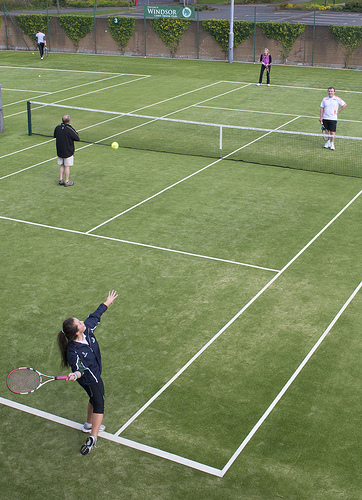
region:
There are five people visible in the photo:
[25, 16, 344, 417]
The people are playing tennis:
[16, 9, 357, 399]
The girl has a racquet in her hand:
[15, 301, 180, 497]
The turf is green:
[21, 166, 359, 458]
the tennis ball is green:
[27, 75, 189, 218]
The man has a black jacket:
[40, 98, 133, 223]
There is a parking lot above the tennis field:
[23, 5, 358, 77]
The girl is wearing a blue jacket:
[23, 274, 170, 453]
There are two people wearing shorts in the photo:
[24, 15, 359, 460]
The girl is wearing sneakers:
[34, 259, 168, 481]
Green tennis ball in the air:
[109, 141, 118, 148]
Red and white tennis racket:
[4, 366, 71, 393]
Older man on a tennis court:
[54, 114, 81, 186]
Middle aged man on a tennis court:
[319, 86, 347, 149]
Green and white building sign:
[143, 6, 195, 20]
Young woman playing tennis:
[46, 289, 120, 455]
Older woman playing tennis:
[256, 47, 270, 85]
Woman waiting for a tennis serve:
[258, 48, 272, 84]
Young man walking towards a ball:
[34, 31, 46, 58]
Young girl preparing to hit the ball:
[55, 288, 115, 452]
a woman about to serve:
[3, 279, 123, 469]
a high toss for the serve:
[105, 139, 125, 154]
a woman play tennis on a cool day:
[53, 278, 123, 459]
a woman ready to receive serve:
[247, 43, 278, 91]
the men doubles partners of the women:
[39, 68, 351, 201]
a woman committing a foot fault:
[4, 284, 127, 467]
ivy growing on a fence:
[10, 17, 321, 63]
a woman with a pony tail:
[4, 282, 125, 466]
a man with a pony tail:
[42, 109, 79, 185]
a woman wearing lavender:
[246, 46, 273, 92]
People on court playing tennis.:
[254, 45, 349, 161]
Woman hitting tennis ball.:
[6, 283, 144, 458]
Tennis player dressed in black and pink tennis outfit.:
[255, 48, 279, 88]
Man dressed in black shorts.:
[317, 116, 340, 132]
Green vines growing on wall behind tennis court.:
[148, 18, 252, 55]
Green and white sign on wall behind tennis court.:
[139, 0, 202, 27]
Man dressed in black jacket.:
[46, 120, 90, 161]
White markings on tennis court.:
[104, 177, 359, 478]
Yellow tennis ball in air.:
[104, 137, 131, 156]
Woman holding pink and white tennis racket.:
[5, 355, 78, 397]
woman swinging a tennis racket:
[3, 273, 132, 467]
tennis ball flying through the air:
[107, 127, 123, 161]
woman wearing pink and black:
[237, 42, 278, 90]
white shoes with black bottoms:
[73, 423, 111, 467]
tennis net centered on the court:
[23, 92, 360, 186]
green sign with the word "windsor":
[136, 5, 200, 32]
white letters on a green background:
[137, 3, 212, 28]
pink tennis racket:
[2, 358, 82, 401]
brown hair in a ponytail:
[49, 314, 82, 372]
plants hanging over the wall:
[55, 11, 98, 58]